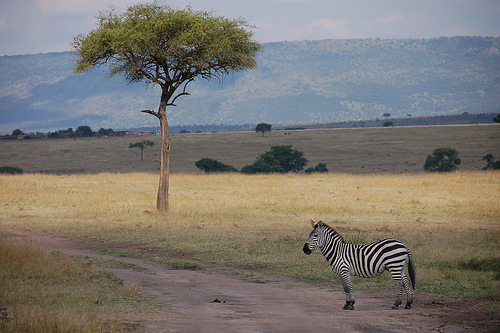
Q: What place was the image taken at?
A: It was taken at the field.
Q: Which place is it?
A: It is a field.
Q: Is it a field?
A: Yes, it is a field.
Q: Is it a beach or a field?
A: It is a field.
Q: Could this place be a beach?
A: No, it is a field.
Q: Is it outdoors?
A: Yes, it is outdoors.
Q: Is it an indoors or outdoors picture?
A: It is outdoors.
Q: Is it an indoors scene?
A: No, it is outdoors.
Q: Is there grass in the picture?
A: Yes, there is grass.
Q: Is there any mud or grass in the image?
A: Yes, there is grass.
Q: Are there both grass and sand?
A: No, there is grass but no sand.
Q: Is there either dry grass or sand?
A: Yes, there is dry grass.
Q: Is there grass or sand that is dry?
A: Yes, the grass is dry.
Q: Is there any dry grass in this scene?
A: Yes, there is dry grass.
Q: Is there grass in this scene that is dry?
A: Yes, there is grass that is dry.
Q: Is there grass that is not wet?
A: Yes, there is dry grass.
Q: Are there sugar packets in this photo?
A: No, there are no sugar packets.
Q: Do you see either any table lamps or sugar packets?
A: No, there are no sugar packets or table lamps.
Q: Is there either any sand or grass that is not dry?
A: No, there is grass but it is dry.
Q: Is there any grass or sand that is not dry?
A: No, there is grass but it is dry.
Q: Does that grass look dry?
A: Yes, the grass is dry.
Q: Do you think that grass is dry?
A: Yes, the grass is dry.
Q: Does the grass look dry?
A: Yes, the grass is dry.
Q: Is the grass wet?
A: No, the grass is dry.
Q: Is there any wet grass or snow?
A: No, there is grass but it is dry.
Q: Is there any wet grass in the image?
A: No, there is grass but it is dry.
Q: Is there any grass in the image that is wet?
A: No, there is grass but it is dry.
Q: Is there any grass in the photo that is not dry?
A: No, there is grass but it is dry.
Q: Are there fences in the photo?
A: No, there are no fences.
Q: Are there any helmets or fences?
A: No, there are no fences or helmets.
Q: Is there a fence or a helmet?
A: No, there are no fences or helmets.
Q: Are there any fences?
A: No, there are no fences.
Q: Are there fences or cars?
A: No, there are no fences or cars.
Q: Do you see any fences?
A: No, there are no fences.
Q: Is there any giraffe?
A: No, there are no giraffes.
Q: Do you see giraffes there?
A: No, there are no giraffes.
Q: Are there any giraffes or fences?
A: No, there are no giraffes or fences.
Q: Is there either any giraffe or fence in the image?
A: No, there are no giraffes or fences.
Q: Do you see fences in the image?
A: No, there are no fences.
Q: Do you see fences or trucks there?
A: No, there are no fences or trucks.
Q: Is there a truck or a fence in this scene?
A: No, there are no fences or trucks.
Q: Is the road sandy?
A: Yes, the road is sandy.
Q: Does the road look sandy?
A: Yes, the road is sandy.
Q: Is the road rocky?
A: No, the road is sandy.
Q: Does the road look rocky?
A: No, the road is sandy.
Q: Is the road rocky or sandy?
A: The road is sandy.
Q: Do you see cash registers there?
A: No, there are no cash registers.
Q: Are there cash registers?
A: No, there are no cash registers.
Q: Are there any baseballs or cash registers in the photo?
A: No, there are no cash registers or baseballs.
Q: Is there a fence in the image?
A: No, there are no fences.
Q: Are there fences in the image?
A: No, there are no fences.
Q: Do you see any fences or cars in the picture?
A: No, there are no fences or cars.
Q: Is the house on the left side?
A: Yes, the house is on the left of the image.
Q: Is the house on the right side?
A: No, the house is on the left of the image.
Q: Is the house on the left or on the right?
A: The house is on the left of the image.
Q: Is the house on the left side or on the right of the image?
A: The house is on the left of the image.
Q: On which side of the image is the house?
A: The house is on the left of the image.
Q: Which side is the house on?
A: The house is on the left of the image.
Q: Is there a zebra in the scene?
A: Yes, there is a zebra.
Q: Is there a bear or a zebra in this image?
A: Yes, there is a zebra.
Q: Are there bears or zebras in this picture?
A: Yes, there is a zebra.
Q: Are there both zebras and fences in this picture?
A: No, there is a zebra but no fences.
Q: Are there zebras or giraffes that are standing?
A: Yes, the zebra is standing.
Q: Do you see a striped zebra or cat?
A: Yes, there is a striped zebra.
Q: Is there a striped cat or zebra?
A: Yes, there is a striped zebra.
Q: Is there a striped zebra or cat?
A: Yes, there is a striped zebra.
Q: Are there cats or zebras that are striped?
A: Yes, the zebra is striped.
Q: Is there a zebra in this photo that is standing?
A: Yes, there is a zebra that is standing.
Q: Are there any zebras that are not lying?
A: Yes, there is a zebra that is standing.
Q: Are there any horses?
A: No, there are no horses.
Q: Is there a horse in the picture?
A: No, there are no horses.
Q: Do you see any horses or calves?
A: No, there are no horses or calves.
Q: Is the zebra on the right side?
A: Yes, the zebra is on the right of the image.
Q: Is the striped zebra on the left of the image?
A: No, the zebra is on the right of the image.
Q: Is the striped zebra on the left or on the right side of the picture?
A: The zebra is on the right of the image.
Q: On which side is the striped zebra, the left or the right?
A: The zebra is on the right of the image.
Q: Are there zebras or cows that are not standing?
A: No, there is a zebra but it is standing.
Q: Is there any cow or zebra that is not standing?
A: No, there is a zebra but it is standing.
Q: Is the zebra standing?
A: Yes, the zebra is standing.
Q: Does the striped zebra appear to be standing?
A: Yes, the zebra is standing.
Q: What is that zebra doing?
A: The zebra is standing.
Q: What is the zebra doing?
A: The zebra is standing.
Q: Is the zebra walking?
A: No, the zebra is standing.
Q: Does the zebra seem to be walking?
A: No, the zebra is standing.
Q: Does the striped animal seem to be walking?
A: No, the zebra is standing.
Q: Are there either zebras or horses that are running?
A: No, there is a zebra but it is standing.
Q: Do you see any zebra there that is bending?
A: No, there is a zebra but it is standing.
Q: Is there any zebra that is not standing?
A: No, there is a zebra but it is standing.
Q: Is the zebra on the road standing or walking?
A: The zebra is standing.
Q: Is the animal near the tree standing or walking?
A: The zebra is standing.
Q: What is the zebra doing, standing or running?
A: The zebra is standing.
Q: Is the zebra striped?
A: Yes, the zebra is striped.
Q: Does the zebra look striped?
A: Yes, the zebra is striped.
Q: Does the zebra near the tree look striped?
A: Yes, the zebra is striped.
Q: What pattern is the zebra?
A: The zebra is striped.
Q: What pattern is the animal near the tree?
A: The zebra is striped.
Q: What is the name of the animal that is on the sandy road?
A: The animal is a zebra.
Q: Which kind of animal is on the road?
A: The animal is a zebra.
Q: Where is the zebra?
A: The zebra is on the road.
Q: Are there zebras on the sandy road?
A: Yes, there is a zebra on the road.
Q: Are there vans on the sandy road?
A: No, there is a zebra on the road.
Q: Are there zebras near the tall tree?
A: Yes, there is a zebra near the tree.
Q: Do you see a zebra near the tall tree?
A: Yes, there is a zebra near the tree.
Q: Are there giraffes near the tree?
A: No, there is a zebra near the tree.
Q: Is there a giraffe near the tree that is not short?
A: No, there is a zebra near the tree.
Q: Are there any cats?
A: No, there are no cats.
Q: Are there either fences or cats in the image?
A: No, there are no cats or fences.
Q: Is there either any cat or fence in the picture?
A: No, there are no cats or fences.